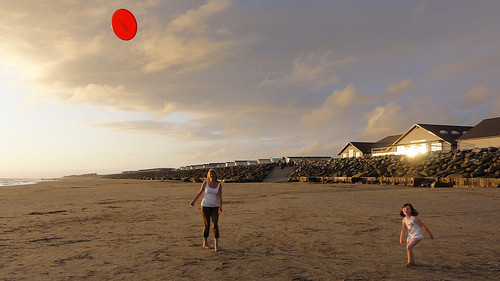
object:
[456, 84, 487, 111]
clouds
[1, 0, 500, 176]
sky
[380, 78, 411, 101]
clouds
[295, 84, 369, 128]
clouds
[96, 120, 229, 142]
clouds